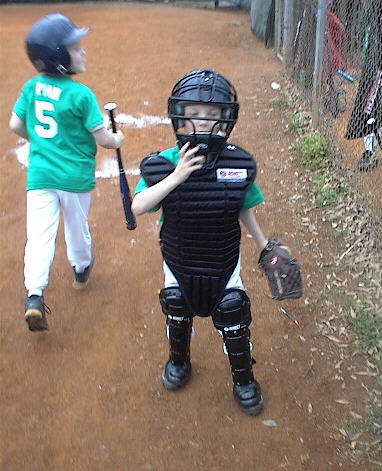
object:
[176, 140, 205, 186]
hand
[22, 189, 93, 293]
white pants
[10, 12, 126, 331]
boy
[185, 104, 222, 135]
face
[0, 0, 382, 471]
ground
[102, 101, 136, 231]
bat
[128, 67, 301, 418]
elephant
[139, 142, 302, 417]
catcher's outfit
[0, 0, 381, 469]
picture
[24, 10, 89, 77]
batter's helmet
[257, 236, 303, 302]
catchers mitt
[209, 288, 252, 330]
knee pad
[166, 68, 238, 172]
helmet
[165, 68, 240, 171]
face mask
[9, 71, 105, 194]
uniform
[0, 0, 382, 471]
field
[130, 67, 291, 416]
boy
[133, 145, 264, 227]
uniform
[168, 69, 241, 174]
gear